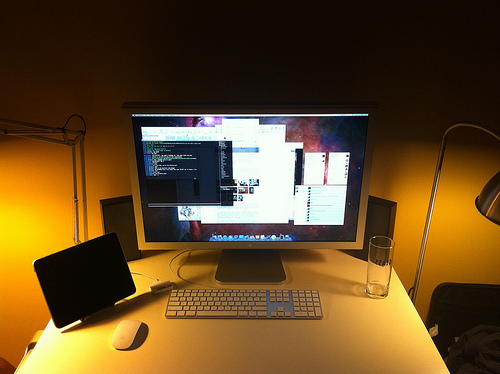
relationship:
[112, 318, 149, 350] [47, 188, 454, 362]
computer mouse on desk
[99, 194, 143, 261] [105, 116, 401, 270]
computer speaker are by monitor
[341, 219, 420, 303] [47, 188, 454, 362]
glass on desk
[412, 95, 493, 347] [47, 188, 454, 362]
floor lamp by desk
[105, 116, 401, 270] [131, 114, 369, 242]
monitor has a monitor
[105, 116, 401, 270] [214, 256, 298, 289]
monitor has a base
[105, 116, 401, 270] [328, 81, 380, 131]
monitor has a corner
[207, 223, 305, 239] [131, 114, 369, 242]
dock on monitor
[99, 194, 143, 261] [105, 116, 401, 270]
computer speaker are behind monitor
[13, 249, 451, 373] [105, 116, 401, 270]
desk by monitor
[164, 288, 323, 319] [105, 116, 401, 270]
computer keyboard in front of monitor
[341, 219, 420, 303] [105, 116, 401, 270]
glass by monitor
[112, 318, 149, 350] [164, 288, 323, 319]
computer mouse by computer keyboard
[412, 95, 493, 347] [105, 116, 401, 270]
floor lamp by monitor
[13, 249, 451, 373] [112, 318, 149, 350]
desk by computer mouse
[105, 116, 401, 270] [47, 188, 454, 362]
monitor on desk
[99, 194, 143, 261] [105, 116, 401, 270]
computer speaker behind monitor